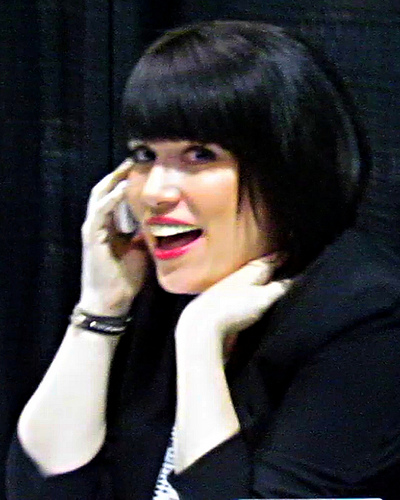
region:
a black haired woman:
[0, 1, 397, 499]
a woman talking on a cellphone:
[1, 21, 397, 499]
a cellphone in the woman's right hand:
[80, 160, 145, 290]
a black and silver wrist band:
[65, 307, 129, 335]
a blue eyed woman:
[129, 143, 217, 165]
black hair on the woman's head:
[124, 19, 372, 283]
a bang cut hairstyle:
[123, 16, 372, 296]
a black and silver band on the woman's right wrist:
[66, 308, 136, 336]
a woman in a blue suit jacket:
[4, 21, 396, 499]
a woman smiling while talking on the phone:
[2, 19, 396, 499]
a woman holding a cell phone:
[8, 13, 398, 498]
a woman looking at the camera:
[2, 5, 395, 498]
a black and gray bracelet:
[52, 295, 148, 349]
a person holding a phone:
[10, 15, 399, 499]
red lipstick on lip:
[137, 208, 211, 265]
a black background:
[0, 3, 394, 301]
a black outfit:
[4, 237, 397, 498]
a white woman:
[18, 1, 397, 498]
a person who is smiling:
[1, 1, 393, 498]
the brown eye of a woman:
[131, 143, 153, 161]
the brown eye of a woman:
[181, 145, 214, 163]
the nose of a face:
[143, 153, 181, 203]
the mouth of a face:
[145, 213, 203, 257]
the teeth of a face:
[148, 222, 197, 235]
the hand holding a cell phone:
[80, 163, 150, 308]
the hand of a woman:
[169, 256, 281, 333]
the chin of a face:
[150, 260, 204, 292]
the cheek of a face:
[183, 169, 244, 217]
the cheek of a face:
[125, 169, 154, 219]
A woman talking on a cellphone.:
[1, 16, 395, 497]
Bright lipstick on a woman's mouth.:
[140, 213, 205, 257]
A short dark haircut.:
[120, 16, 372, 276]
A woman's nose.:
[140, 156, 180, 204]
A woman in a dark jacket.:
[0, 16, 396, 493]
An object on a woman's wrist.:
[68, 300, 128, 336]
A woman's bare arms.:
[16, 304, 292, 472]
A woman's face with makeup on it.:
[121, 136, 273, 292]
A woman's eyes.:
[124, 140, 217, 168]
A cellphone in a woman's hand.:
[81, 156, 145, 295]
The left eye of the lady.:
[126, 143, 159, 164]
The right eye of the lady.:
[177, 140, 220, 166]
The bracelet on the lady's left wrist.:
[66, 305, 134, 333]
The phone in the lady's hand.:
[115, 196, 135, 233]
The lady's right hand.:
[184, 247, 290, 322]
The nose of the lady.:
[133, 165, 186, 208]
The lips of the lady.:
[140, 207, 204, 264]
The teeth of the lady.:
[149, 226, 191, 236]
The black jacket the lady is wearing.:
[48, 211, 394, 497]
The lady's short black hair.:
[123, 36, 368, 260]